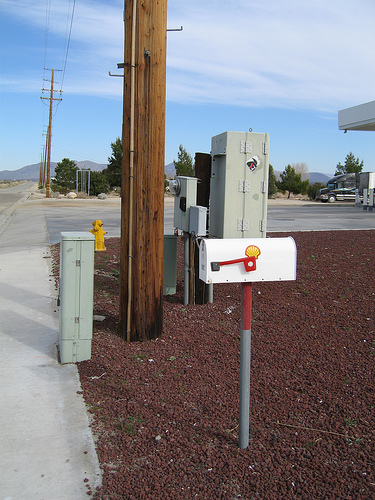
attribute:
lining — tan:
[124, 0, 137, 342]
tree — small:
[276, 166, 302, 200]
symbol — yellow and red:
[241, 242, 263, 263]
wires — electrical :
[40, 0, 93, 140]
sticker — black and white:
[243, 150, 269, 176]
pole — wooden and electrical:
[119, 2, 166, 333]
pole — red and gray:
[232, 284, 257, 452]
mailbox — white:
[191, 235, 298, 446]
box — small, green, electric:
[41, 225, 122, 377]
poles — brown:
[35, 66, 68, 193]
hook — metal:
[166, 22, 184, 33]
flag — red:
[211, 252, 258, 273]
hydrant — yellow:
[88, 217, 108, 251]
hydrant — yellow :
[86, 217, 109, 255]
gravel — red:
[113, 223, 372, 324]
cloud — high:
[0, 0, 374, 109]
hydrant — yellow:
[89, 215, 112, 260]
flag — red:
[201, 249, 256, 274]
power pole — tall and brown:
[44, 64, 56, 190]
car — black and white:
[318, 186, 362, 203]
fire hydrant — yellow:
[88, 215, 111, 254]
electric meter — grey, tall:
[167, 174, 209, 240]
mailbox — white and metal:
[184, 231, 307, 299]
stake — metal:
[195, 230, 274, 328]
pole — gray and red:
[178, 281, 271, 481]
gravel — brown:
[0, 306, 160, 500]